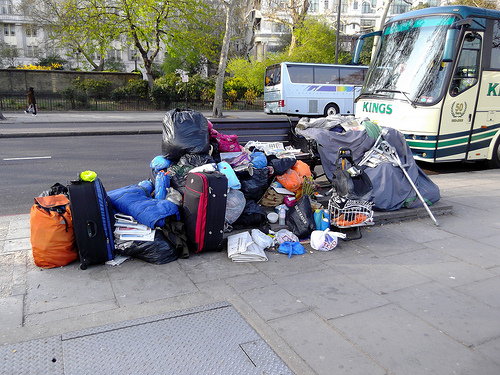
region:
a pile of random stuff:
[31, 80, 456, 298]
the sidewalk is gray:
[10, 182, 495, 354]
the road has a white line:
[2, 128, 67, 218]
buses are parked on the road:
[250, 5, 495, 197]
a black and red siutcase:
[174, 158, 254, 264]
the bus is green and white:
[331, 3, 493, 203]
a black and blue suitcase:
[56, 157, 130, 285]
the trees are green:
[41, 5, 372, 102]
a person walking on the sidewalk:
[7, 76, 157, 151]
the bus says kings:
[344, 89, 414, 140]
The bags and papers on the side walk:
[27, 77, 469, 279]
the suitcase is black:
[150, 160, 243, 273]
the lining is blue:
[81, 167, 121, 272]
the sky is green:
[233, 46, 273, 102]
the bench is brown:
[226, 105, 332, 185]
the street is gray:
[180, 252, 422, 372]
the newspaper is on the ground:
[220, 222, 319, 272]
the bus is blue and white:
[356, 10, 499, 194]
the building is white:
[6, 15, 77, 87]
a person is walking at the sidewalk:
[0, 65, 125, 127]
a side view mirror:
[341, 28, 368, 70]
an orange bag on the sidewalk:
[26, 185, 71, 277]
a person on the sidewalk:
[20, 83, 42, 120]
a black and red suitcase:
[176, 167, 231, 252]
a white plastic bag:
[303, 227, 352, 259]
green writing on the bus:
[357, 99, 393, 119]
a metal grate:
[1, 296, 303, 373]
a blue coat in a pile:
[105, 183, 186, 231]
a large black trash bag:
[153, 103, 211, 160]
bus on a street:
[339, 2, 498, 179]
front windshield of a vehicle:
[354, 8, 467, 112]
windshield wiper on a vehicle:
[373, 86, 424, 111]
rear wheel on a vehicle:
[320, 97, 345, 122]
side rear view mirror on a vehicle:
[347, 27, 387, 72]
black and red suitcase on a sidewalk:
[175, 165, 237, 265]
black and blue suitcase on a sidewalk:
[63, 167, 123, 277]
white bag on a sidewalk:
[302, 224, 352, 261]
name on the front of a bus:
[357, 97, 399, 122]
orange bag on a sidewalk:
[24, 187, 86, 275]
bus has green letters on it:
[350, 91, 410, 123]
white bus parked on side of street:
[255, 43, 372, 127]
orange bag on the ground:
[16, 179, 88, 271]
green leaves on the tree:
[61, 0, 235, 84]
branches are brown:
[118, 13, 161, 98]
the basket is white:
[328, 199, 387, 239]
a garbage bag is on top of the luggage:
[140, 101, 255, 183]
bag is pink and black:
[173, 164, 243, 269]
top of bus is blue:
[368, 0, 495, 45]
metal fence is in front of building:
[8, 67, 236, 122]